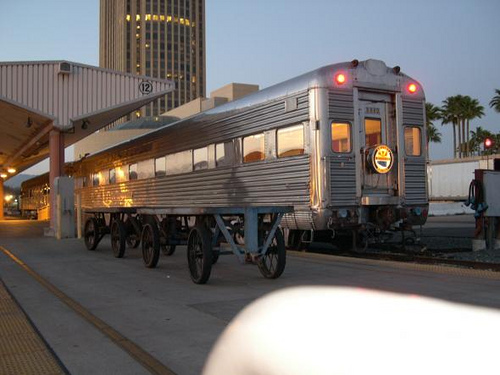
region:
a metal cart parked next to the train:
[80, 203, 293, 285]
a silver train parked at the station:
[12, 57, 432, 257]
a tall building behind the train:
[98, 0, 207, 130]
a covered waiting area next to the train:
[1, 58, 176, 235]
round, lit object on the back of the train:
[367, 141, 393, 174]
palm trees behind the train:
[423, 90, 499, 156]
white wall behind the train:
[427, 151, 498, 200]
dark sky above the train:
[1, 0, 498, 173]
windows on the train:
[16, 118, 421, 199]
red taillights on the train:
[335, 73, 415, 93]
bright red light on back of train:
[329, 69, 349, 89]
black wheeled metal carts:
[78, 199, 298, 286]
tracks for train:
[283, 226, 499, 280]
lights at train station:
[2, 162, 21, 189]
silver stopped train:
[15, 58, 445, 250]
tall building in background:
[94, 0, 210, 133]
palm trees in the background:
[423, 89, 498, 161]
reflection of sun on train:
[15, 149, 139, 220]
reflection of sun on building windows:
[124, 1, 200, 118]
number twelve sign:
[135, 77, 155, 96]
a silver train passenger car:
[73, 55, 431, 255]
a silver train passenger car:
[15, 155, 75, 210]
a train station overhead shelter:
[3, 56, 180, 234]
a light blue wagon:
[138, 192, 293, 285]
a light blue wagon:
[73, 200, 174, 260]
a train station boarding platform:
[0, 215, 496, 373]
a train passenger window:
[275, 123, 302, 158]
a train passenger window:
[240, 130, 262, 161]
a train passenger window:
[212, 140, 237, 165]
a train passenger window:
[193, 147, 209, 171]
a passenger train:
[128, 36, 460, 248]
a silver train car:
[85, 30, 453, 267]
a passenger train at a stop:
[2, 55, 452, 318]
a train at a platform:
[0, 52, 415, 286]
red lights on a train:
[328, 64, 428, 101]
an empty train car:
[129, 25, 454, 297]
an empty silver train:
[128, 33, 483, 263]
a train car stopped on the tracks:
[160, 34, 479, 271]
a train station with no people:
[3, 1, 491, 373]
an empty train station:
[3, 0, 498, 315]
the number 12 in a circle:
[134, 75, 157, 97]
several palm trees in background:
[426, 83, 498, 158]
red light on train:
[333, 69, 350, 87]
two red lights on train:
[332, 67, 422, 97]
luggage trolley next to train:
[77, 198, 297, 280]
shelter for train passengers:
[0, 55, 177, 242]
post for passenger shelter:
[45, 122, 67, 238]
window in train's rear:
[273, 122, 308, 162]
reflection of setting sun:
[108, 155, 139, 207]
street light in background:
[480, 135, 495, 151]